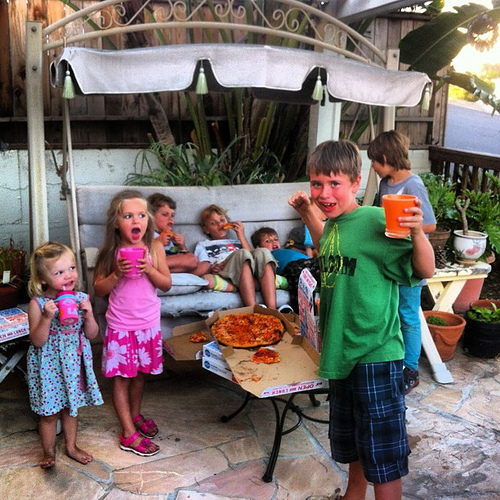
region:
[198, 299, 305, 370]
pizza in the box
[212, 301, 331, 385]
pizza in the box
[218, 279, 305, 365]
pizza in the box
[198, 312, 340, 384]
pizza in the box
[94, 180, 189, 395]
girl is holding a cup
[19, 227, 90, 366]
girl is holding a cup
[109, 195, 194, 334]
girl is holding a cup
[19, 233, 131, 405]
girl is holding a cup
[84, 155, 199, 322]
girl is holding a cup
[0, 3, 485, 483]
scene of a kid's pizza party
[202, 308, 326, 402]
red pizza in a cardboard box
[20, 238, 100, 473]
little girl with bare feet and a blue dress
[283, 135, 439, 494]
boy with plaid blue shorts and a green tee shirt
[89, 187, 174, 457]
young girl with pink sandles, shorts and shirt with long hair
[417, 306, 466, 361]
brown flower pot with dirt in it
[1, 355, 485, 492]
flat stone paved patio area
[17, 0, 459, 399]
tan metal framed swinging bench seat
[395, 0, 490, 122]
green foliage hanging over the patio area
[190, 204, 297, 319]
boy on the swinging bench with tan pants and a white shirt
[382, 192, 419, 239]
an orange glass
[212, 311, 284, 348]
a pepperoni pizza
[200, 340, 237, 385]
the edges of two pizza boxes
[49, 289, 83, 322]
a pink and blue sippie cup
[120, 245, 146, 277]
a pink cup in a girl's hands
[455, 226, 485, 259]
a white ceramic vase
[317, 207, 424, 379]
a green shirt on a boy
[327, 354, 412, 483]
a blue plaid pair of shorts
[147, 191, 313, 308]
three boys sitting on a swing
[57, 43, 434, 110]
a white canvas canopy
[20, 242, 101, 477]
this is a child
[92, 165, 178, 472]
this is a child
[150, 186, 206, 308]
this is a child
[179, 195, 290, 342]
this is a child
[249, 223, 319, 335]
this is a child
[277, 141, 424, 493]
this is a child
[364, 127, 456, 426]
this is a child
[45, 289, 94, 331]
the child is carrying a cup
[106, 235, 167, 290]
the child is carrying a cup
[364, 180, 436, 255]
the child is carrying a cup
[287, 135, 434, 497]
A boy wearing blue shorts and a green shirt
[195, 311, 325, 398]
A stack of pizza boxes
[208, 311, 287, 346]
A complete pizza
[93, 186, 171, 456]
A girl wearing a lot of pink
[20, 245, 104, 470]
A girl wearing a blue dress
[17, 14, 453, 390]
A outdoor swinging chair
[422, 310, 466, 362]
A flower pot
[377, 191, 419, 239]
An orange cup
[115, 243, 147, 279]
A pink cup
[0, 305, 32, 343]
A pizza box